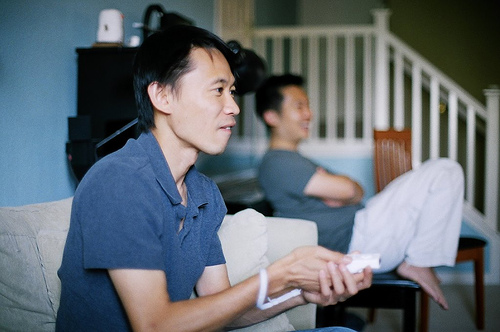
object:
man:
[50, 20, 378, 331]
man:
[250, 69, 468, 312]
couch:
[0, 192, 324, 332]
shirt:
[51, 123, 232, 331]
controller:
[252, 250, 387, 313]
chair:
[369, 127, 492, 332]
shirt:
[252, 146, 368, 257]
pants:
[343, 155, 470, 278]